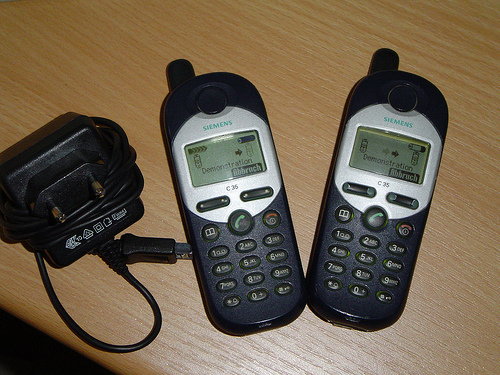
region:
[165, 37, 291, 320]
this is a black phone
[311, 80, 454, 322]
this is a black phone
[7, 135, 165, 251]
that is a charger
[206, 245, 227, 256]
that is a button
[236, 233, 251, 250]
that is a button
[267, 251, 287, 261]
that is a button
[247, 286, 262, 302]
that is a button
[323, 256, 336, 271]
that is a button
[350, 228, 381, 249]
that is a button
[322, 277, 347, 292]
that is a button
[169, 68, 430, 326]
the phones are two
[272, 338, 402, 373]
the table is brown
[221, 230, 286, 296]
the buttons are black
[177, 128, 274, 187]
the screen is small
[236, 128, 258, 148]
the battery is fully charged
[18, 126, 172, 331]
the charger is black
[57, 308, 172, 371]
the cable is black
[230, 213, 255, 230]
the call button is green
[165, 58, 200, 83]
the antenna is small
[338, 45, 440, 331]
the phone is on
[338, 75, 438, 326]
the phone is black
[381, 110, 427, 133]
siemens are on the phone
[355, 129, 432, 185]
the screen is small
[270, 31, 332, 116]
the surface is brown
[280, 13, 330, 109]
the surface is wooden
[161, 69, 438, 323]
the phones are close together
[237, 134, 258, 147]
the battery is full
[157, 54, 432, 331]
the phones are black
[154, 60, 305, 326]
the phone is old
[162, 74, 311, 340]
the model of phone is siemens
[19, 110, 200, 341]
charger is on the table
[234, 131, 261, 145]
battery is fully charged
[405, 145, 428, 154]
the battery uis half empty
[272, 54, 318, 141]
the surface is wooden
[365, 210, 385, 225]
the call sign is blue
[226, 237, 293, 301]
the numbers are white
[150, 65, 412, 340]
two phones on table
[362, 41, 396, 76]
black antennas on phones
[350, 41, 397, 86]
short and black antennas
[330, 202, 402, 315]
black buttons on phones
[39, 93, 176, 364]
small black charging unit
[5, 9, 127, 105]
table is light brown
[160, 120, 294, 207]
small LCD screen on phone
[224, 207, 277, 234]
red and green power buttons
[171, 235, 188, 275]
silver adapter for power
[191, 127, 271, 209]
grey frame around information window